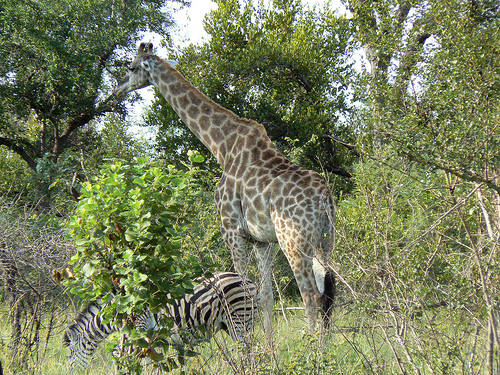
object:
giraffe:
[114, 42, 343, 340]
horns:
[136, 42, 143, 51]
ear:
[140, 61, 153, 72]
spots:
[256, 177, 272, 193]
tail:
[325, 185, 337, 318]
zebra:
[62, 268, 260, 374]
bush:
[55, 149, 221, 375]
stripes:
[228, 306, 259, 314]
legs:
[250, 240, 276, 344]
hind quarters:
[268, 173, 325, 266]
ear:
[67, 327, 75, 341]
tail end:
[320, 272, 336, 325]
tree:
[0, 0, 174, 176]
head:
[111, 42, 160, 96]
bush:
[0, 187, 80, 375]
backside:
[218, 271, 259, 325]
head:
[62, 326, 89, 375]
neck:
[149, 57, 238, 165]